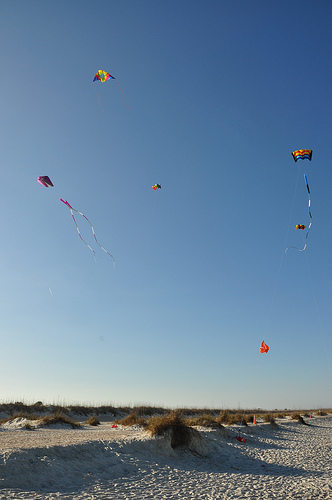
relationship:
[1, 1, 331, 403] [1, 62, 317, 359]
sky full of kites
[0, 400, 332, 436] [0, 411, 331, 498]
grass in sand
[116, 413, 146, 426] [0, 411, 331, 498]
grass in sand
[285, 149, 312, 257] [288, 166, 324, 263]
kite with long tail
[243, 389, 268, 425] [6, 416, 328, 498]
cone sitting on sand dune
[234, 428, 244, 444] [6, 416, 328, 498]
person sitting in front sand dune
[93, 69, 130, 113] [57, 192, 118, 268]
kite with tail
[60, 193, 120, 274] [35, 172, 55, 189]
striped tail of kite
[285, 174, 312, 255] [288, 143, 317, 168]
long tail of kite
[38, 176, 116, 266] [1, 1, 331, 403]
kite in sky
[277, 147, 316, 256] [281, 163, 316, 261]
kite with tail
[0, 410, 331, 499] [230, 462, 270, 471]
beach with prints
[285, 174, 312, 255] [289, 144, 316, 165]
long tail on kite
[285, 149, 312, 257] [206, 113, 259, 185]
kite on sky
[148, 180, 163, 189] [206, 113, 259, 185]
kite on sky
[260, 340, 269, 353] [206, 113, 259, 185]
colorful kite on sky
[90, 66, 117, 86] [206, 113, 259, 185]
kite on sky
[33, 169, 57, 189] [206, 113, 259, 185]
kite on sky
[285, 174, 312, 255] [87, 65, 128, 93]
long tail of kite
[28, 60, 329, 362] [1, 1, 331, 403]
kites in sky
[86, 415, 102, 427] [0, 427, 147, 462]
plant growing in sand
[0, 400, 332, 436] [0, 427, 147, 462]
plant growing in sand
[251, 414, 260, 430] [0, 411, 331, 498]
item on sand